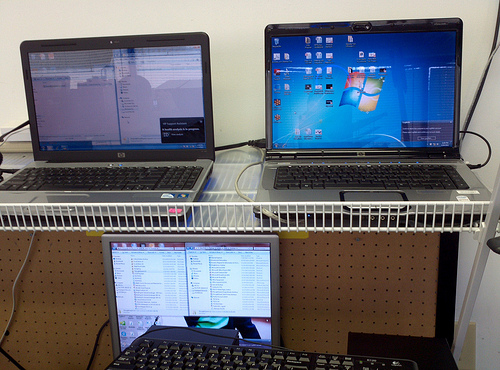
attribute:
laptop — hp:
[1, 31, 215, 221]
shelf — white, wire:
[2, 152, 494, 234]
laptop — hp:
[252, 16, 499, 221]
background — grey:
[32, 52, 203, 144]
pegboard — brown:
[1, 221, 439, 369]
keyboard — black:
[107, 338, 422, 369]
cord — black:
[462, 2, 499, 169]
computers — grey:
[4, 18, 493, 360]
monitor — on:
[103, 231, 282, 363]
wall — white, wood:
[1, 3, 500, 185]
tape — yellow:
[85, 225, 309, 239]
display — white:
[3, 126, 499, 369]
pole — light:
[451, 165, 500, 363]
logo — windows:
[337, 66, 387, 117]